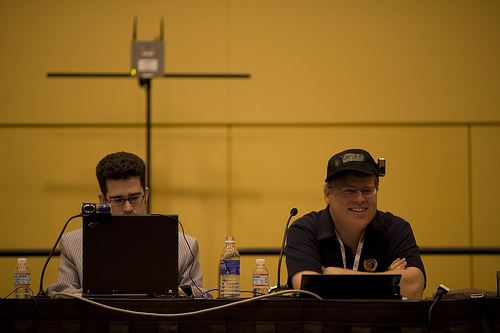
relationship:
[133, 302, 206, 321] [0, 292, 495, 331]
cord on table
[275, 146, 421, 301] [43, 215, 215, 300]
man wearing suit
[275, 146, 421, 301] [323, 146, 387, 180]
man with hat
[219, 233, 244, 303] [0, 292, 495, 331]
water on table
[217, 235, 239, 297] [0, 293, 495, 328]
bottle on table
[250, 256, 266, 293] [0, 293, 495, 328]
bottle on table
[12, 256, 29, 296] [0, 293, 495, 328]
bottle on table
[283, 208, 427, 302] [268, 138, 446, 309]
shirt on man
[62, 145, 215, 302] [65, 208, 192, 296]
man sitting behind computer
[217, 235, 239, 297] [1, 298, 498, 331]
bottle on table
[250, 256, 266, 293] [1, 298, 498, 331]
bottle on table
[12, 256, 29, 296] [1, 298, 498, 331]
bottle on table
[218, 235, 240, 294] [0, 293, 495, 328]
water bottle on table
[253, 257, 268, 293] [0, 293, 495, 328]
water bottle on table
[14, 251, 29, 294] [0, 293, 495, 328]
water bottle on table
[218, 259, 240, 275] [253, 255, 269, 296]
label on water bottle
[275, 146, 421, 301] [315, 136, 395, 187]
man wearing hat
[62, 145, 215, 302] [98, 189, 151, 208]
man wearing eyeglasses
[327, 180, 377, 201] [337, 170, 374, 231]
glasses on face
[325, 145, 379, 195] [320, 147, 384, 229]
hat on head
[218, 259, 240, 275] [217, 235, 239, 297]
label on bottle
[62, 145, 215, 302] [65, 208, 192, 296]
man looking at computer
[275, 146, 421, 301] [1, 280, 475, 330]
man at table